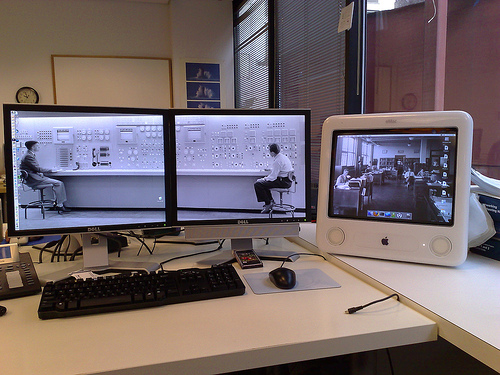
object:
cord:
[345, 293, 400, 314]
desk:
[0, 221, 439, 375]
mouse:
[268, 267, 296, 289]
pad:
[243, 268, 341, 294]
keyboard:
[38, 262, 246, 320]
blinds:
[273, 0, 346, 185]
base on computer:
[38, 233, 159, 287]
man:
[254, 143, 295, 214]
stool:
[269, 171, 298, 219]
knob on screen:
[326, 227, 345, 246]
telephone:
[0, 242, 42, 301]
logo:
[381, 236, 389, 245]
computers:
[170, 109, 313, 268]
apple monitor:
[328, 127, 457, 227]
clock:
[15, 86, 39, 104]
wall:
[0, 0, 234, 109]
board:
[52, 57, 173, 107]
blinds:
[234, 7, 270, 109]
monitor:
[175, 115, 307, 221]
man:
[19, 140, 72, 212]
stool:
[18, 169, 64, 219]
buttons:
[24, 270, 30, 273]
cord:
[280, 252, 326, 268]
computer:
[1, 104, 172, 287]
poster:
[185, 62, 220, 82]